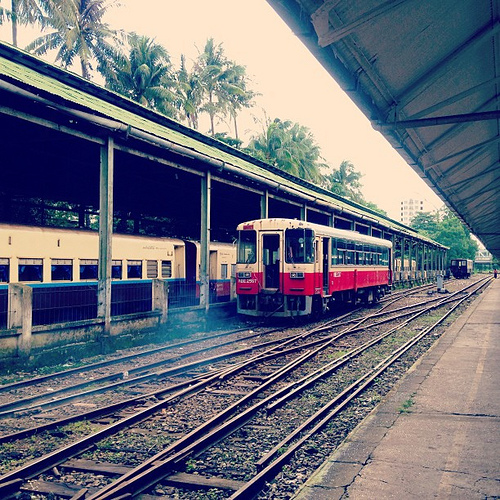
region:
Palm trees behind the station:
[98, 1, 370, 210]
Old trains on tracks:
[8, 207, 410, 322]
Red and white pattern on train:
[220, 209, 404, 326]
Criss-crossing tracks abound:
[31, 308, 433, 439]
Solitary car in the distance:
[441, 248, 492, 290]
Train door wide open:
[304, 219, 348, 319]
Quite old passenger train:
[229, 215, 409, 327]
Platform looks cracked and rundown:
[278, 247, 468, 497]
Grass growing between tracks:
[6, 411, 226, 482]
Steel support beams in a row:
[54, 167, 459, 309]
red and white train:
[241, 207, 403, 319]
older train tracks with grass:
[14, 336, 384, 478]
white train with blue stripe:
[4, 235, 217, 289]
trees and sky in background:
[245, 127, 479, 244]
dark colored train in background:
[448, 242, 488, 277]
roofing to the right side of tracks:
[390, 130, 498, 261]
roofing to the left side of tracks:
[33, 132, 406, 220]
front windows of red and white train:
[253, 222, 288, 299]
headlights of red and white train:
[224, 267, 324, 304]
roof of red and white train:
[237, 208, 407, 243]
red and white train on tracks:
[216, 211, 414, 328]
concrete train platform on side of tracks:
[369, 328, 499, 498]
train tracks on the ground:
[149, 348, 344, 468]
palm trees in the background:
[66, 44, 262, 131]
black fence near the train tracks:
[25, 281, 108, 327]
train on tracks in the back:
[447, 251, 483, 283]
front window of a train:
[282, 226, 319, 269]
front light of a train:
[288, 266, 307, 288]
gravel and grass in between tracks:
[274, 400, 309, 425]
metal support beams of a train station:
[92, 142, 119, 339]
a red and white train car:
[231, 220, 394, 322]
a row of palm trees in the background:
[2, 1, 396, 217]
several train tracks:
[3, 271, 490, 498]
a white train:
[1, 222, 416, 335]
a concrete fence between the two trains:
[2, 276, 247, 353]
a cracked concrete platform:
[291, 263, 498, 498]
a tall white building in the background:
[398, 196, 426, 232]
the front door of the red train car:
[257, 228, 281, 291]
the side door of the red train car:
[318, 233, 333, 297]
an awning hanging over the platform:
[267, 0, 499, 274]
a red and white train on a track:
[216, 215, 397, 324]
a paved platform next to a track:
[292, 271, 496, 495]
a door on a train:
[256, 228, 281, 295]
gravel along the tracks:
[206, 384, 330, 476]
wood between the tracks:
[56, 455, 136, 479]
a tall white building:
[397, 194, 423, 227]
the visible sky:
[1, 1, 491, 256]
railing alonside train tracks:
[106, 277, 156, 315]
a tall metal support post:
[96, 133, 117, 330]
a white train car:
[1, 221, 186, 324]